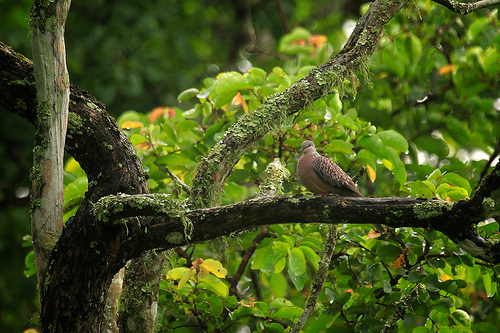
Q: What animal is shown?
A: A bird.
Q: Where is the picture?
A: In a tree.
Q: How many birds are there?
A: One.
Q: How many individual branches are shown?
A: Four.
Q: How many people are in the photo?
A: Zero.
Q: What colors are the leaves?
A: Green and orange.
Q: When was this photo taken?
A: Daytime.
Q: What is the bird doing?
A: Standing still.